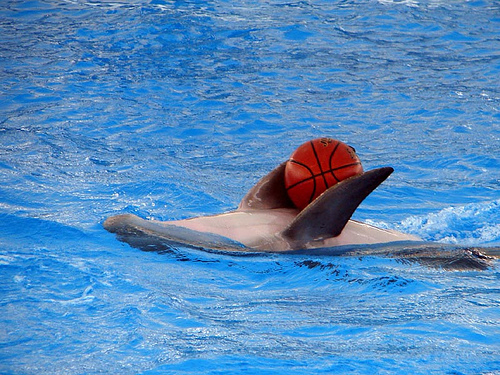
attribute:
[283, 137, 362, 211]
basketball — orange, wet, striped, orang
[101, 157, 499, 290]
dolphin — on back, doing trick, gray, flipped over, cute, upside down, dark gray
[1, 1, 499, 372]
water — clear, blue, light blue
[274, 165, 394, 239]
flipper — gray, dark gray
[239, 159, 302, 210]
flipper — gray, dark gray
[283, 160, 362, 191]
stripe — black, straight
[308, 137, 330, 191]
stripe — black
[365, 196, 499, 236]
wave — white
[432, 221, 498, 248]
wave — white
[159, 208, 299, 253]
chest — light pink